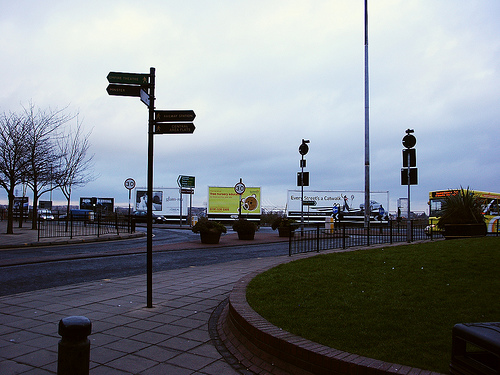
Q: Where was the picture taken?
A: It was taken at the walkway.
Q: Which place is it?
A: It is a walkway.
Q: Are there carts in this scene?
A: No, there are no carts.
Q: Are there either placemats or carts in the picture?
A: No, there are no carts or placemats.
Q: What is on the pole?
A: The sign is on the pole.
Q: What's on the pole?
A: The sign is on the pole.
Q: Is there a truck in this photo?
A: No, there are no trucks.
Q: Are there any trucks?
A: No, there are no trucks.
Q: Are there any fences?
A: Yes, there is a fence.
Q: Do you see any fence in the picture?
A: Yes, there is a fence.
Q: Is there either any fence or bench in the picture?
A: Yes, there is a fence.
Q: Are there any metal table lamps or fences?
A: Yes, there is a metal fence.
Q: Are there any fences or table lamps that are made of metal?
A: Yes, the fence is made of metal.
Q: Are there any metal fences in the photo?
A: Yes, there is a metal fence.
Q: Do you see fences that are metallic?
A: Yes, there is a fence that is metallic.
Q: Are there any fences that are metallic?
A: Yes, there is a fence that is metallic.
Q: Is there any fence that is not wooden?
A: Yes, there is a metallic fence.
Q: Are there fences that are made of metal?
A: Yes, there is a fence that is made of metal.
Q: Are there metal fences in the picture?
A: Yes, there is a fence that is made of metal.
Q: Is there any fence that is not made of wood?
A: Yes, there is a fence that is made of metal.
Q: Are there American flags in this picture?
A: No, there are no American flags.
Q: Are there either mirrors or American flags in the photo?
A: No, there are no American flags or mirrors.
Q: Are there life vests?
A: No, there are no life vests.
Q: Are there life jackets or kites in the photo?
A: No, there are no life jackets or kites.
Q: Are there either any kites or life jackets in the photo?
A: No, there are no life jackets or kites.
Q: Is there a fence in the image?
A: Yes, there is a fence.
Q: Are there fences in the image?
A: Yes, there is a fence.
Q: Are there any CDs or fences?
A: Yes, there is a fence.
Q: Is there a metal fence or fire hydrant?
A: Yes, there is a metal fence.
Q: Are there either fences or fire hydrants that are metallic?
A: Yes, the fence is metallic.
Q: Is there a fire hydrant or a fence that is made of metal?
A: Yes, the fence is made of metal.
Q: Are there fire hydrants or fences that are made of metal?
A: Yes, the fence is made of metal.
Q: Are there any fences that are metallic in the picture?
A: Yes, there is a metal fence.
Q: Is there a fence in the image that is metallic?
A: Yes, there is a fence that is metallic.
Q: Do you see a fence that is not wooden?
A: Yes, there is a metallic fence.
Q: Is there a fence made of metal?
A: Yes, there is a fence that is made of metal.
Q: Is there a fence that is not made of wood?
A: Yes, there is a fence that is made of metal.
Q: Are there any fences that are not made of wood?
A: Yes, there is a fence that is made of metal.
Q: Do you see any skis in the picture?
A: No, there are no skis.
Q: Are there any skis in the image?
A: No, there are no skis.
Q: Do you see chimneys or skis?
A: No, there are no skis or chimneys.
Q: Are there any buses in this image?
A: Yes, there is a bus.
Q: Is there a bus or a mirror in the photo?
A: Yes, there is a bus.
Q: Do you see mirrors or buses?
A: Yes, there is a bus.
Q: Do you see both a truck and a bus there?
A: No, there is a bus but no trucks.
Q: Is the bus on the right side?
A: Yes, the bus is on the right of the image.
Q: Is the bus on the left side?
A: No, the bus is on the right of the image.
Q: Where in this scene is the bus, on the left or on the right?
A: The bus is on the right of the image.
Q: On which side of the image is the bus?
A: The bus is on the right of the image.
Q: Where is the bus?
A: The bus is on the road.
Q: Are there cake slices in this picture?
A: No, there are no cake slices.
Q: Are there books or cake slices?
A: No, there are no cake slices or books.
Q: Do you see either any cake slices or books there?
A: No, there are no cake slices or books.